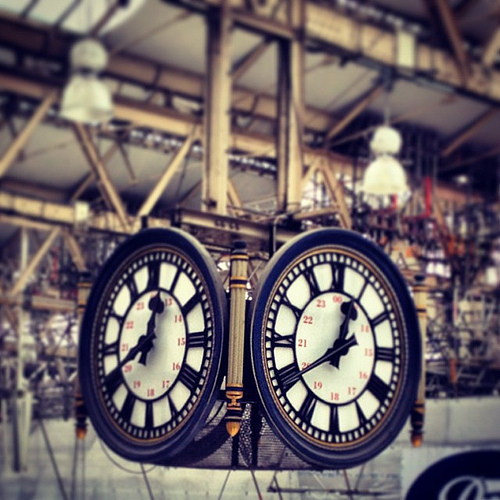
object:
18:
[330, 392, 339, 400]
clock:
[244, 226, 425, 470]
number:
[327, 260, 347, 291]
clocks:
[75, 225, 223, 467]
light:
[58, 27, 113, 133]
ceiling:
[1, 0, 500, 112]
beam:
[202, 14, 230, 183]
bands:
[292, 29, 306, 40]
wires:
[397, 102, 429, 122]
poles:
[273, 56, 305, 207]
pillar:
[223, 230, 251, 359]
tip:
[224, 413, 242, 438]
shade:
[358, 154, 411, 208]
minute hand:
[103, 330, 152, 393]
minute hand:
[288, 337, 359, 396]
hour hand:
[329, 298, 358, 370]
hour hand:
[145, 287, 166, 338]